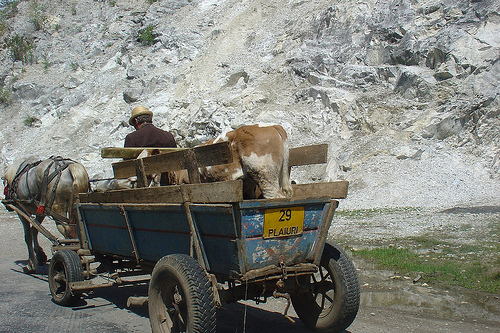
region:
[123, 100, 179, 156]
this is a man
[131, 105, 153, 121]
this is a hat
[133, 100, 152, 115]
the hat is brown in color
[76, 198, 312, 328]
this is a chart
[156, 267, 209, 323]
this is the wheel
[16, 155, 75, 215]
this is a horse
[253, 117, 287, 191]
this is a cow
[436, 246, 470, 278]
this is a grass area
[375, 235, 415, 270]
the grass is green in color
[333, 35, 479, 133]
this is a rock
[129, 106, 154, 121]
the man is wearing a hat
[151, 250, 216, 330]
the wheel is made of rubber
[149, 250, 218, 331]
the wheel is black in color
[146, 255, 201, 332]
the wheel is full of dirt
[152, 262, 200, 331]
the dirt is brown in color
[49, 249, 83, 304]
the wheel is made of rubber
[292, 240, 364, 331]
the wheel is made of rubber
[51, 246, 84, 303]
the wheel is black in color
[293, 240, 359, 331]
the wheel is black in color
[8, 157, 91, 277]
a horse is pulling the cart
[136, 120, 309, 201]
Cow in the back of a cart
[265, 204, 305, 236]
Yellow license plate on a cart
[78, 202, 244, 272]
Blue wooden side of a cart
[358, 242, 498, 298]
Green grass in the road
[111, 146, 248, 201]
Wooden fence around a cart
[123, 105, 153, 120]
Brown hat on a man's head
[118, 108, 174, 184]
Man driving a horse cart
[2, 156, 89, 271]
White horse pulling a cart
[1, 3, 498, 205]
Rocks on a hill side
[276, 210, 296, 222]
29 on a license plate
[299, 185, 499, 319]
Grassy area covered with rock dust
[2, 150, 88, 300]
Brown horse pulling wagon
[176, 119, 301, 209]
Brown and white cow in wagon being pulled by horse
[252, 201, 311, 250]
Gold license plate on wagon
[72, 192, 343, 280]
Blue wooden wagon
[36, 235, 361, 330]
Wheels of wagon looking a little bent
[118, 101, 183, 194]
Man driver of horse pulled wagon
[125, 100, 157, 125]
Gold top hat worn by man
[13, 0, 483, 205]
Dusty limestone type mountain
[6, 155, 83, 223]
Harness straps on horse to guide it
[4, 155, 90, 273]
A horse pulling a carriage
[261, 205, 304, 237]
A yellow sign on the back of the carriage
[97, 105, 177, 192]
A man driving the carriage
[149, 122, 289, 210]
A cow in the back of the carriage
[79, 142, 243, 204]
Woo planks at the side of the carriage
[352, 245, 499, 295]
A patch of green grass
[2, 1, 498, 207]
The rocky side of a mountain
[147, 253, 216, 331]
One of the carriage's back wheels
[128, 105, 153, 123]
A light colored hat on a person's head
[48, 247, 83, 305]
One of the front wheels of the carriage